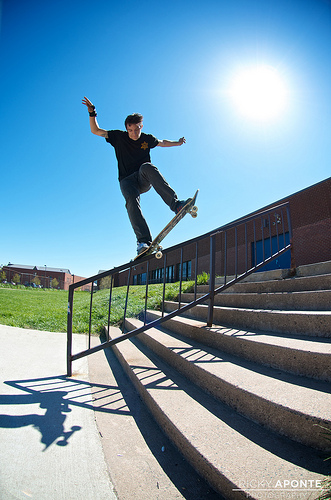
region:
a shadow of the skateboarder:
[0, 373, 135, 450]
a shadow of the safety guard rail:
[3, 326, 263, 409]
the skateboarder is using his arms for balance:
[79, 95, 185, 148]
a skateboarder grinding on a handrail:
[80, 94, 198, 262]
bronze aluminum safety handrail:
[65, 200, 293, 376]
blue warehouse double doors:
[251, 231, 290, 268]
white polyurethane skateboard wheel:
[154, 251, 162, 259]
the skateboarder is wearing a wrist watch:
[86, 109, 97, 117]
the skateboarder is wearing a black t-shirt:
[104, 130, 158, 174]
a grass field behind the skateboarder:
[0, 264, 194, 331]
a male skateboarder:
[76, 95, 194, 255]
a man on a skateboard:
[75, 95, 205, 266]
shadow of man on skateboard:
[1, 384, 80, 444]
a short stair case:
[93, 266, 327, 496]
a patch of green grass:
[0, 271, 195, 333]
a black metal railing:
[65, 198, 292, 384]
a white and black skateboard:
[127, 190, 201, 265]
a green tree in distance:
[28, 275, 40, 287]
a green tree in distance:
[47, 273, 58, 287]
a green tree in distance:
[8, 271, 22, 286]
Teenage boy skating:
[76, 96, 217, 260]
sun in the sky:
[190, 34, 318, 162]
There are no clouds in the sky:
[25, 14, 188, 83]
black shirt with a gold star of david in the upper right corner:
[99, 126, 176, 168]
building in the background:
[1, 252, 93, 290]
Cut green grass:
[18, 290, 61, 317]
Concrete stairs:
[175, 259, 318, 469]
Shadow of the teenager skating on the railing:
[2, 356, 129, 450]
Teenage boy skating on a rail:
[76, 98, 266, 328]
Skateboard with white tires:
[134, 186, 218, 252]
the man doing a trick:
[79, 91, 199, 258]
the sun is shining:
[211, 50, 287, 127]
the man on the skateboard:
[78, 94, 204, 271]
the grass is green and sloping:
[6, 279, 50, 322]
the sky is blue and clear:
[40, 17, 152, 66]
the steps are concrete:
[116, 265, 319, 468]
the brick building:
[5, 254, 99, 294]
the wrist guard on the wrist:
[83, 102, 104, 121]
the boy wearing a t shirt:
[100, 124, 174, 178]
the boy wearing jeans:
[112, 171, 195, 253]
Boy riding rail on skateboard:
[81, 97, 199, 263]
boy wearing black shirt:
[80, 95, 200, 264]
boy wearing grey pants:
[81, 100, 192, 253]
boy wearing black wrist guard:
[81, 92, 196, 259]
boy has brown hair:
[81, 101, 200, 266]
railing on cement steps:
[66, 212, 330, 457]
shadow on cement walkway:
[0, 377, 123, 450]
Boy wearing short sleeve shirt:
[82, 95, 194, 265]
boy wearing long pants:
[80, 98, 194, 254]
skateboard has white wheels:
[129, 190, 202, 260]